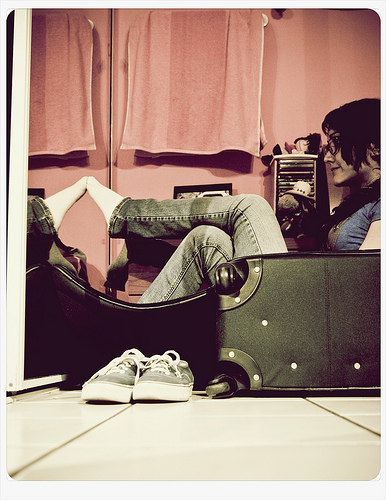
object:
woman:
[85, 97, 378, 306]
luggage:
[207, 250, 385, 396]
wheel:
[201, 366, 234, 403]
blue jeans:
[105, 196, 287, 303]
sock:
[85, 174, 125, 234]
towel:
[118, 14, 269, 158]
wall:
[113, 11, 386, 276]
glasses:
[318, 141, 343, 155]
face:
[321, 131, 353, 190]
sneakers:
[132, 345, 194, 407]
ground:
[15, 394, 381, 483]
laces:
[92, 345, 146, 373]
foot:
[42, 177, 87, 232]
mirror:
[15, 12, 116, 283]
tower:
[270, 153, 323, 239]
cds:
[276, 160, 312, 227]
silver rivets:
[285, 357, 302, 372]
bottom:
[206, 366, 380, 395]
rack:
[111, 11, 275, 29]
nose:
[321, 150, 333, 166]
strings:
[143, 350, 182, 375]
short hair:
[321, 96, 384, 174]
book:
[270, 148, 319, 165]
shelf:
[269, 148, 327, 236]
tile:
[63, 413, 378, 448]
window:
[120, 29, 265, 151]